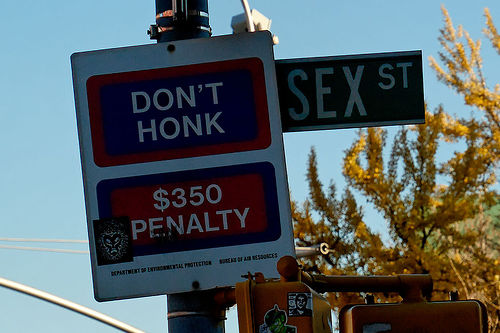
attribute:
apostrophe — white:
[196, 82, 203, 95]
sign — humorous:
[267, 47, 429, 137]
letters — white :
[119, 87, 227, 114]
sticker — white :
[286, 291, 313, 316]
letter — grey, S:
[284, 63, 312, 124]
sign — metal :
[74, 20, 346, 304]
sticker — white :
[255, 299, 319, 327]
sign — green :
[276, 47, 426, 132]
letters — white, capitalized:
[122, 209, 251, 238]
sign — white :
[64, 27, 296, 296]